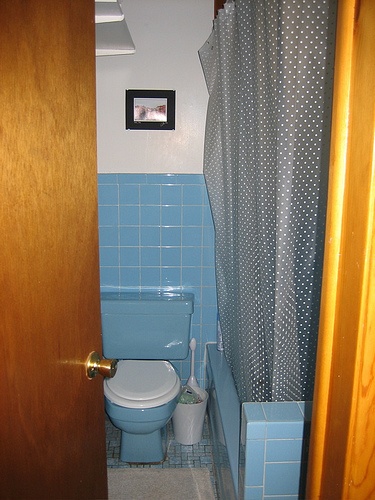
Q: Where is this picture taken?
A: A bathroom.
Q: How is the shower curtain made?
A: Of plastic.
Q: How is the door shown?
A: Open.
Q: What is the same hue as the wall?
A: The toilet.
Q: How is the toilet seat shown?
A: Down.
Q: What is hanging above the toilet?
A: A picture.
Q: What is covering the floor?
A: Blue tile.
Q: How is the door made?
A: Of wood.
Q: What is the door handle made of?
A: Brass.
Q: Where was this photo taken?
A: In a house.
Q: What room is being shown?
A: Bathroom.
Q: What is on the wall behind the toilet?
A: Tile.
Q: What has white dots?
A: Shower curtain.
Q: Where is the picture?
A: On the wall.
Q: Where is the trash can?
A: Between the toilet and tub.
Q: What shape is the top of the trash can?
A: Round.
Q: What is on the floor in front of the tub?
A: Rug.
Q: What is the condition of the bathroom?
A: Clean.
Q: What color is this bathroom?
A: Blue.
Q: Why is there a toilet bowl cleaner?
A: To clean the toilet.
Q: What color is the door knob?
A: Brass.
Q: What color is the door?
A: Brown.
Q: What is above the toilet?
A: A picture.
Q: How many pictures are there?
A: 1.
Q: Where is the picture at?
A: Above the toilet.